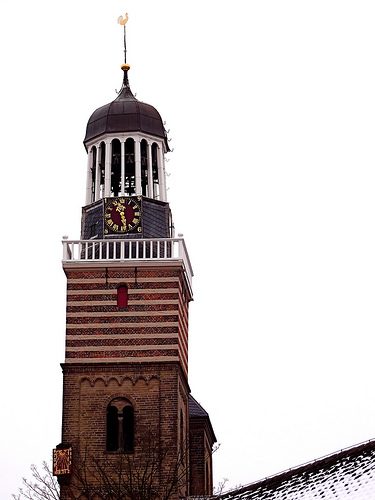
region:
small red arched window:
[114, 279, 130, 309]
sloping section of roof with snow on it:
[218, 441, 374, 499]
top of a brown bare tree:
[15, 429, 241, 499]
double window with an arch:
[103, 394, 137, 457]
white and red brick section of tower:
[66, 264, 182, 362]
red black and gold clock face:
[106, 190, 141, 233]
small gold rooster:
[116, 12, 129, 27]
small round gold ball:
[121, 61, 130, 72]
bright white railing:
[60, 235, 184, 260]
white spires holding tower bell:
[77, 131, 173, 202]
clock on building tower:
[96, 190, 146, 239]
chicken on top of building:
[111, 8, 137, 33]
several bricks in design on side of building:
[142, 287, 183, 315]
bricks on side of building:
[67, 396, 99, 415]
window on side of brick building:
[95, 390, 146, 461]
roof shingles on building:
[306, 445, 364, 490]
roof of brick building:
[181, 387, 229, 445]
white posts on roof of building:
[99, 138, 118, 168]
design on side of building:
[49, 438, 76, 478]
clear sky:
[232, 237, 304, 300]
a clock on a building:
[77, 159, 173, 285]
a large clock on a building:
[86, 191, 144, 276]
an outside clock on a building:
[96, 170, 150, 277]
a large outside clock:
[100, 192, 158, 271]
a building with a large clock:
[80, 178, 168, 268]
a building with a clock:
[99, 169, 164, 310]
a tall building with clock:
[55, 188, 179, 401]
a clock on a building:
[95, 188, 150, 231]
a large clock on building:
[94, 192, 185, 260]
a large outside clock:
[110, 181, 139, 247]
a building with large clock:
[106, 189, 145, 252]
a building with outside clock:
[108, 193, 157, 250]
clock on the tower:
[103, 199, 140, 236]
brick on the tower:
[166, 425, 172, 430]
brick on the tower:
[164, 441, 178, 449]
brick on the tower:
[159, 395, 166, 402]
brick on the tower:
[137, 394, 148, 397]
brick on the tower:
[86, 461, 98, 467]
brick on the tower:
[91, 417, 104, 423]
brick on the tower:
[94, 405, 110, 413]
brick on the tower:
[144, 408, 153, 415]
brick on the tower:
[146, 393, 156, 402]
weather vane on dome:
[84, 14, 169, 139]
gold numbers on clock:
[105, 198, 140, 231]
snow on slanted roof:
[220, 440, 373, 499]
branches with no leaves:
[12, 436, 226, 499]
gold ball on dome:
[82, 63, 172, 144]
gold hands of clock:
[115, 201, 126, 227]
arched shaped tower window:
[104, 392, 138, 454]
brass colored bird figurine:
[116, 12, 130, 26]